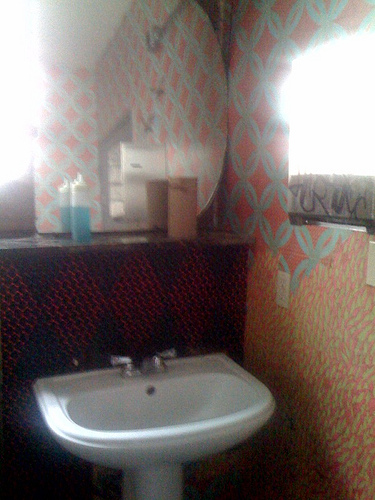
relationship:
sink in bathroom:
[16, 347, 290, 500] [6, 5, 374, 498]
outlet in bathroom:
[272, 261, 297, 316] [6, 5, 374, 498]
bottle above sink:
[61, 167, 100, 244] [16, 347, 290, 500]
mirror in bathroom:
[276, 38, 374, 246] [6, 5, 374, 498]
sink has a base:
[16, 347, 290, 500] [112, 466, 189, 499]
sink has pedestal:
[16, 347, 290, 500] [112, 466, 189, 499]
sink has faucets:
[16, 347, 290, 500] [104, 338, 185, 381]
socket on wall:
[272, 261, 297, 316] [276, 221, 367, 499]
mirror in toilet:
[276, 38, 374, 246] [6, 5, 374, 498]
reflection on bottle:
[53, 167, 71, 239] [61, 167, 100, 244]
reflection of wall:
[86, 20, 229, 159] [210, 9, 286, 234]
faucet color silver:
[137, 348, 174, 378] [104, 338, 185, 381]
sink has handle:
[16, 347, 290, 500] [104, 338, 185, 381]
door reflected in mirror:
[90, 110, 140, 234] [42, 2, 244, 227]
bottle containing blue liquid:
[61, 167, 100, 244] [68, 206, 93, 245]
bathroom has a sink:
[6, 5, 374, 498] [16, 347, 290, 500]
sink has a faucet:
[16, 347, 290, 500] [137, 348, 174, 378]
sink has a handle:
[16, 347, 290, 500] [105, 347, 138, 381]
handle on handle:
[160, 342, 181, 363] [158, 349, 176, 358]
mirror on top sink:
[42, 2, 244, 227] [16, 347, 290, 500]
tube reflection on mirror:
[162, 167, 209, 250] [42, 2, 244, 227]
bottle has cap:
[61, 167, 100, 244] [72, 167, 90, 186]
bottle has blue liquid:
[61, 167, 100, 244] [68, 206, 93, 245]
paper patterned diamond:
[232, 7, 365, 484] [229, 118, 263, 166]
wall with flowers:
[210, 9, 286, 234] [232, 27, 277, 198]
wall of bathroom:
[210, 9, 286, 234] [6, 5, 374, 498]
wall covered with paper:
[210, 9, 286, 234] [232, 7, 365, 484]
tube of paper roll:
[162, 167, 209, 250] [165, 170, 199, 240]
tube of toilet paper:
[162, 167, 209, 250] [159, 163, 206, 238]